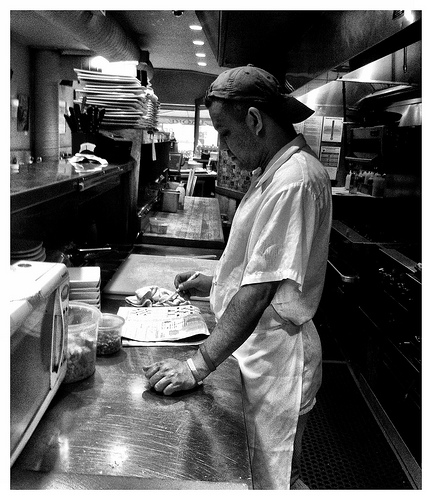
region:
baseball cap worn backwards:
[207, 63, 316, 129]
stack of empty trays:
[69, 69, 151, 128]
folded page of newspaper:
[116, 304, 210, 367]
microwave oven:
[7, 261, 66, 472]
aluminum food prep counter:
[24, 252, 249, 492]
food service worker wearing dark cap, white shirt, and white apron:
[139, 60, 331, 492]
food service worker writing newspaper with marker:
[111, 58, 327, 491]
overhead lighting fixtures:
[180, 14, 207, 74]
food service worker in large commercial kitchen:
[11, 9, 421, 491]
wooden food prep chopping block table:
[136, 193, 223, 253]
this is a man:
[165, 64, 402, 457]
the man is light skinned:
[221, 300, 257, 340]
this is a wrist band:
[193, 341, 215, 372]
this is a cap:
[224, 65, 282, 94]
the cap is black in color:
[233, 70, 268, 106]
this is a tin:
[69, 309, 103, 370]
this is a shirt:
[279, 171, 319, 232]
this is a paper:
[143, 312, 194, 337]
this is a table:
[81, 415, 181, 477]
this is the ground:
[329, 421, 389, 474]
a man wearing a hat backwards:
[199, 61, 307, 176]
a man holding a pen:
[134, 263, 202, 319]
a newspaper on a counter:
[98, 288, 211, 362]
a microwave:
[6, 265, 63, 475]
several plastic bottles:
[336, 166, 383, 193]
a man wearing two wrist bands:
[180, 335, 219, 384]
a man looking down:
[211, 68, 279, 178]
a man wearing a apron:
[246, 167, 316, 412]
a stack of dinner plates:
[70, 262, 103, 318]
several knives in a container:
[58, 98, 109, 141]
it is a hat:
[203, 63, 291, 109]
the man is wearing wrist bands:
[186, 340, 213, 384]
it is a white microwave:
[0, 263, 70, 446]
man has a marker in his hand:
[176, 269, 201, 291]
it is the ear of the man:
[245, 105, 266, 135]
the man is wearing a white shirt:
[235, 181, 324, 279]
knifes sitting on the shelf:
[66, 101, 106, 144]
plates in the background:
[12, 239, 53, 259]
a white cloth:
[126, 285, 184, 306]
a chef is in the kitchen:
[203, 57, 327, 339]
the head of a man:
[200, 57, 326, 178]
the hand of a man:
[138, 352, 194, 401]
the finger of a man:
[139, 363, 161, 382]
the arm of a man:
[189, 187, 313, 386]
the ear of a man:
[241, 102, 265, 138]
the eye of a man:
[217, 124, 237, 140]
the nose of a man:
[215, 134, 227, 154]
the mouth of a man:
[224, 149, 240, 165]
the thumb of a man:
[139, 359, 161, 371]